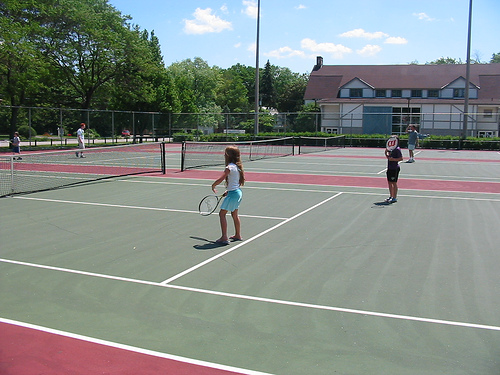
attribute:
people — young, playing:
[187, 141, 402, 238]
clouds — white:
[278, 9, 409, 79]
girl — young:
[204, 141, 276, 262]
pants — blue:
[219, 185, 241, 212]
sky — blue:
[114, 2, 496, 95]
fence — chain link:
[5, 92, 499, 152]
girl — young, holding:
[185, 140, 270, 261]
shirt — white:
[219, 162, 247, 195]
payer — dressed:
[67, 124, 97, 164]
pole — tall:
[459, 1, 476, 147]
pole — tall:
[252, 0, 267, 138]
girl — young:
[202, 140, 257, 245]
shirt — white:
[221, 163, 243, 193]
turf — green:
[403, 222, 460, 262]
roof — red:
[307, 53, 497, 103]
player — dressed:
[385, 137, 401, 206]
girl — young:
[191, 131, 262, 251]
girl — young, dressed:
[201, 145, 262, 245]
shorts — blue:
[222, 187, 245, 213]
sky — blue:
[115, 1, 497, 73]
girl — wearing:
[371, 123, 405, 209]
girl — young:
[200, 134, 256, 264]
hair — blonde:
[223, 138, 258, 180]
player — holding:
[198, 130, 257, 248]